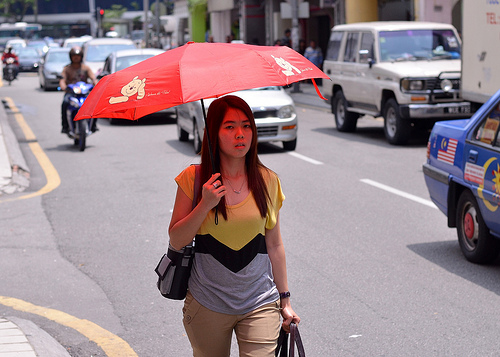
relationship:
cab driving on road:
[420, 81, 500, 275] [302, 142, 419, 340]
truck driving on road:
[319, 20, 469, 146] [291, 153, 427, 335]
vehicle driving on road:
[170, 38, 304, 161] [293, 160, 427, 353]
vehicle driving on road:
[77, 27, 133, 108] [293, 150, 443, 340]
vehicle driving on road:
[36, 44, 86, 109] [293, 160, 427, 353]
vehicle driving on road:
[5, 36, 43, 70] [294, 147, 430, 341]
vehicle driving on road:
[5, 30, 27, 58] [294, 145, 394, 346]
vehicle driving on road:
[58, 30, 96, 53] [294, 150, 419, 349]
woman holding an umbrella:
[140, 88, 295, 352] [62, 25, 333, 144]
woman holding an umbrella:
[165, 88, 300, 356] [68, 20, 358, 161]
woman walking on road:
[165, 88, 300, 356] [294, 147, 430, 341]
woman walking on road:
[140, 88, 295, 352] [114, 122, 423, 341]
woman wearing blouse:
[165, 88, 300, 356] [172, 162, 287, 315]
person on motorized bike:
[67, 51, 96, 94] [64, 99, 91, 192]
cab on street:
[420, 81, 500, 275] [4, 100, 478, 300]